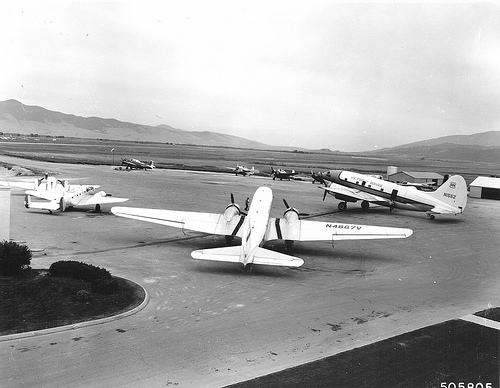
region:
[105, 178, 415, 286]
Airplane sitting on the runway.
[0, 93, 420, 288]
Mountain range next to airport.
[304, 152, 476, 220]
Plane with wheels sitting on the runway.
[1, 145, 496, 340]
Planes lined up on a runway.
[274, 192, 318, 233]
Stationary propeller on an airplane.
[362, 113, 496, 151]
Rounded mountains in the distance.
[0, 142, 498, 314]
Runway with airplanes at a small airport.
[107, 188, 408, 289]
Airplane with black writing on plane wing.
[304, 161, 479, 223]
Small plane with strip painted down the middle.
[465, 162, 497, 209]
White building with dark colored door.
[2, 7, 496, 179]
bright sky with clouds over mountains and airport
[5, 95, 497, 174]
flat land in front of mountains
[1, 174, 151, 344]
edge of building behind curve of bushes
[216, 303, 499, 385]
dark surface with white line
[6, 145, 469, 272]
airplanes forming a loose circle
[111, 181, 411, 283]
flat tail and wings behind propellers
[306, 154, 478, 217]
stripe along middle of plane with curved tail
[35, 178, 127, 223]
slanted and angled wing along body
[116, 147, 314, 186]
planes at edge of paved sirport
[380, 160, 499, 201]
flat and circular structures behind airplane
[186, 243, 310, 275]
ART OF TAIL SECTION OF PLANE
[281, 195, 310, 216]
PROPELLAR OF AIR PLANE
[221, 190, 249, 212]
PROPELLAR OF AIR PLANE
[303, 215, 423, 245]
WING OF AIR PL;ANE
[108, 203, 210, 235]
WING OF AIR PLANE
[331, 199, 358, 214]
WHEEL OF AN AIR PLANE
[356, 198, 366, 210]
WHEEL OF AN AIR PLANE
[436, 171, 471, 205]
PART OF AN AIR PLANE'S TAIL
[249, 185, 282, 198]
NOSE OF AN AIR PLANE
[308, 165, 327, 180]
NOSE OF AN AIR PLANE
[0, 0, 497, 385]
the photo is black and white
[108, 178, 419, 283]
the plane is white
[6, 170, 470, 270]
the planes are packed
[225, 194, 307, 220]
the plane has propellers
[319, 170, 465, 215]
the plane is black and white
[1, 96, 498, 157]
the mountain in the distance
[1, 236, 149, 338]
a patch of plants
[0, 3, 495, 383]
the scene takes place outdoors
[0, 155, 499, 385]
the planes are at the airport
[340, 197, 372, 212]
the plane has wheels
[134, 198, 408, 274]
vintage plane sitting on tarmac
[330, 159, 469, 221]
vintage plane sitting on tarmac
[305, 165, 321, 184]
vintage plane sitting on tarmac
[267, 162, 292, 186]
vintage plane sitting on tarmac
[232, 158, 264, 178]
vintage plane sitting on tarmac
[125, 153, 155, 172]
vintage plane sitting on tarmac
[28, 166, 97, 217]
vintage plane sitting on tarmac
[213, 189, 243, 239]
propeller on plane's wing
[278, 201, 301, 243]
propeller on plane's wing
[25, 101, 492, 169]
mountains in the distance